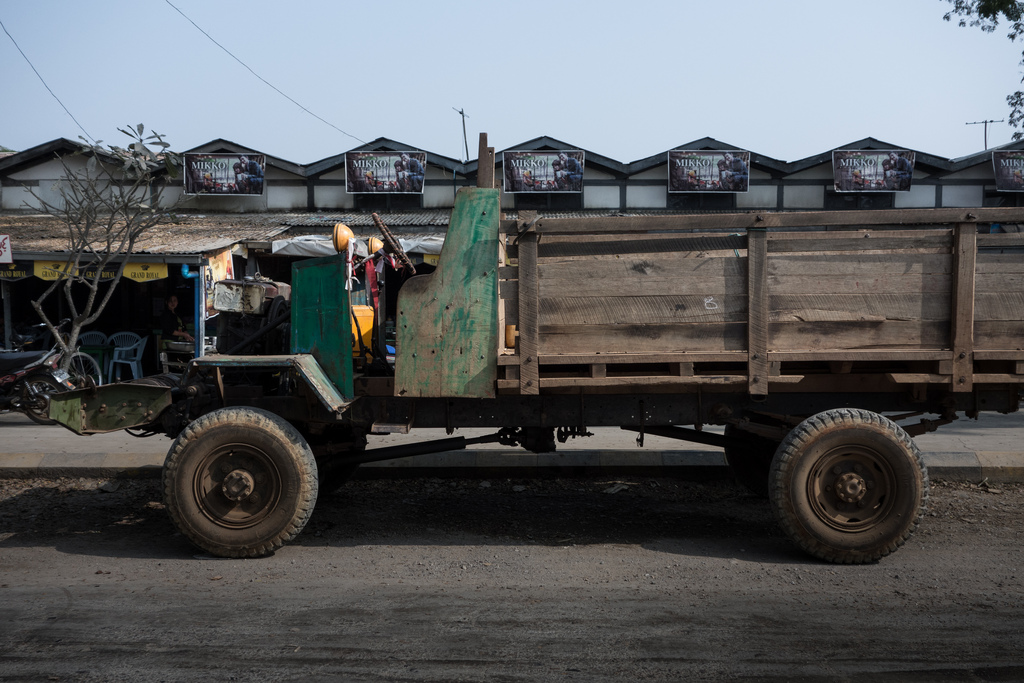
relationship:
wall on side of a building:
[311, 146, 467, 203] [305, 125, 480, 211]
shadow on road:
[356, 476, 733, 570] [0, 407, 1019, 674]